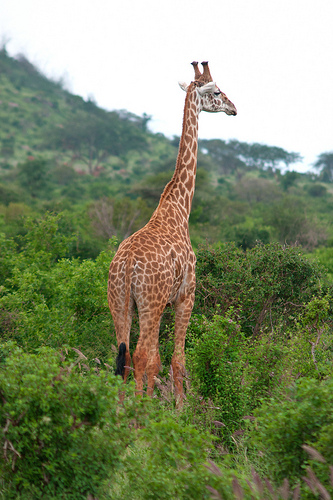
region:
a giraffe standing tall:
[103, 47, 239, 419]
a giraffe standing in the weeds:
[91, 29, 242, 416]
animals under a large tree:
[28, 149, 145, 181]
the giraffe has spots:
[171, 205, 185, 250]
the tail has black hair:
[108, 329, 130, 379]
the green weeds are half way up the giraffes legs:
[125, 340, 223, 410]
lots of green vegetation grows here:
[9, 228, 97, 452]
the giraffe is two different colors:
[135, 237, 175, 278]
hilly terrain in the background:
[3, 46, 169, 159]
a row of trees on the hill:
[202, 134, 303, 176]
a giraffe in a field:
[46, 44, 277, 407]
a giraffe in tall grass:
[9, 43, 281, 438]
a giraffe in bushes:
[40, 55, 300, 436]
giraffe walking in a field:
[26, 50, 279, 437]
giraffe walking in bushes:
[33, 45, 290, 426]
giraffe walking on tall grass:
[59, 45, 329, 412]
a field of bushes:
[22, 329, 282, 497]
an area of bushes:
[18, 304, 223, 498]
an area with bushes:
[7, 242, 331, 498]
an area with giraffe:
[14, 49, 321, 435]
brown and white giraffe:
[101, 47, 244, 417]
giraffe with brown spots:
[85, 49, 248, 399]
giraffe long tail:
[93, 242, 134, 381]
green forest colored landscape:
[0, 161, 90, 372]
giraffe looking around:
[76, 39, 233, 406]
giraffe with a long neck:
[106, 51, 257, 212]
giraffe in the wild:
[15, 47, 305, 486]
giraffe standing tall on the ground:
[72, 41, 224, 420]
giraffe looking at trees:
[39, 39, 285, 426]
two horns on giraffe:
[158, 57, 249, 125]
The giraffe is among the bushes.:
[30, 60, 310, 420]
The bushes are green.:
[7, 329, 94, 474]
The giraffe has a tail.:
[110, 270, 134, 379]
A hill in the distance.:
[12, 53, 163, 178]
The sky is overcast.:
[66, 32, 214, 50]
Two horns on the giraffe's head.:
[186, 53, 211, 75]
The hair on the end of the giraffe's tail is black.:
[107, 337, 129, 378]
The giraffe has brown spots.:
[145, 235, 169, 266]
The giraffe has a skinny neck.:
[159, 113, 204, 193]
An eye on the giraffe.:
[209, 85, 221, 97]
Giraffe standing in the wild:
[97, 52, 239, 422]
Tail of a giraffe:
[112, 252, 132, 377]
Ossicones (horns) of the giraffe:
[184, 55, 212, 75]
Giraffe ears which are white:
[174, 76, 215, 92]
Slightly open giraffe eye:
[214, 88, 221, 96]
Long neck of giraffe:
[174, 105, 198, 227]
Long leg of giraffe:
[133, 276, 167, 411]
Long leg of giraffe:
[174, 261, 196, 412]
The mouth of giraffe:
[225, 102, 239, 119]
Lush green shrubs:
[210, 225, 331, 484]